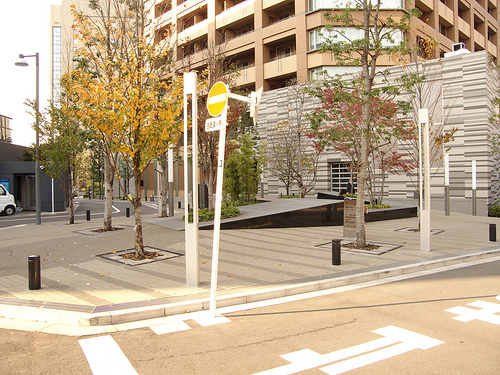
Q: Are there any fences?
A: No, there are no fences.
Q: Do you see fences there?
A: No, there are no fences.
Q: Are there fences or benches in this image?
A: No, there are no fences or benches.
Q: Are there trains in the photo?
A: No, there are no trains.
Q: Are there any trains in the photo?
A: No, there are no trains.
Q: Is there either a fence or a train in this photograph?
A: No, there are no trains or fences.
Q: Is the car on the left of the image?
A: Yes, the car is on the left of the image.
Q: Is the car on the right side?
A: No, the car is on the left of the image.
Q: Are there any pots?
A: No, there are no pots.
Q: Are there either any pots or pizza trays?
A: No, there are no pots or pizza trays.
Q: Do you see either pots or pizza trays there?
A: No, there are no pots or pizza trays.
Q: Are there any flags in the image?
A: No, there are no flags.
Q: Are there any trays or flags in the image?
A: No, there are no flags or trays.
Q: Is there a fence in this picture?
A: No, there are no fences.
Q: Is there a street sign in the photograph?
A: Yes, there is a street sign.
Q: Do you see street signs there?
A: Yes, there is a street sign.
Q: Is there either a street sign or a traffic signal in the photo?
A: Yes, there is a street sign.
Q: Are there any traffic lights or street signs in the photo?
A: Yes, there is a street sign.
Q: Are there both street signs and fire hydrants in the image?
A: No, there is a street sign but no fire hydrants.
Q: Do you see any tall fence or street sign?
A: Yes, there is a tall street sign.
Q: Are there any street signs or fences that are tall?
A: Yes, the street sign is tall.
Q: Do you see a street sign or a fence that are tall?
A: Yes, the street sign is tall.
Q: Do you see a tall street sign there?
A: Yes, there is a tall street sign.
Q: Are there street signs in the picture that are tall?
A: Yes, there is a street sign that is tall.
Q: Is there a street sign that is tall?
A: Yes, there is a street sign that is tall.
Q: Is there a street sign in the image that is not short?
A: Yes, there is a tall street sign.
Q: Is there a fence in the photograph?
A: No, there are no fences.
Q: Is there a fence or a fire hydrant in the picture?
A: No, there are no fences or fire hydrants.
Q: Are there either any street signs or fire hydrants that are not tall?
A: No, there is a street sign but it is tall.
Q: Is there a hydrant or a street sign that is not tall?
A: No, there is a street sign but it is tall.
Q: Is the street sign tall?
A: Yes, the street sign is tall.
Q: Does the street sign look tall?
A: Yes, the street sign is tall.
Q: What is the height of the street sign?
A: The street sign is tall.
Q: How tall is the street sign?
A: The street sign is tall.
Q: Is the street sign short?
A: No, the street sign is tall.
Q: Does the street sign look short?
A: No, the street sign is tall.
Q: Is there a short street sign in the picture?
A: No, there is a street sign but it is tall.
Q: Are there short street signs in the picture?
A: No, there is a street sign but it is tall.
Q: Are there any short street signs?
A: No, there is a street sign but it is tall.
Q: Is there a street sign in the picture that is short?
A: No, there is a street sign but it is tall.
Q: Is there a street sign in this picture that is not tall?
A: No, there is a street sign but it is tall.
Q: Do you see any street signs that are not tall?
A: No, there is a street sign but it is tall.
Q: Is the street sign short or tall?
A: The street sign is tall.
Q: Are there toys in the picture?
A: No, there are no toys.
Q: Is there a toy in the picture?
A: No, there are no toys.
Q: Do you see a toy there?
A: No, there are no toys.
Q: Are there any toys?
A: No, there are no toys.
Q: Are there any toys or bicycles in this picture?
A: No, there are no toys or bicycles.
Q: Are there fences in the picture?
A: No, there are no fences.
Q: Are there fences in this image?
A: No, there are no fences.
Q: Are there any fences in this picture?
A: No, there are no fences.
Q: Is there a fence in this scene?
A: No, there are no fences.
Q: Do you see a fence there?
A: No, there are no fences.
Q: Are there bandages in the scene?
A: No, there are no bandages.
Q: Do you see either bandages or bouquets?
A: No, there are no bandages or bouquets.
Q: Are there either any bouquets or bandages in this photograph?
A: No, there are no bandages or bouquets.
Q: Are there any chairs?
A: No, there are no chairs.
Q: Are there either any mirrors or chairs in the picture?
A: No, there are no chairs or mirrors.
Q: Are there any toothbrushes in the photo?
A: No, there are no toothbrushes.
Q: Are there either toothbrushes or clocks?
A: No, there are no toothbrushes or clocks.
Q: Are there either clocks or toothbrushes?
A: No, there are no toothbrushes or clocks.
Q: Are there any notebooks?
A: No, there are no notebooks.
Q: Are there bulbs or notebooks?
A: No, there are no notebooks or bulbs.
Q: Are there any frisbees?
A: No, there are no frisbees.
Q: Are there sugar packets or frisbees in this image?
A: No, there are no frisbees or sugar packets.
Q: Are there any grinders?
A: No, there are no grinders.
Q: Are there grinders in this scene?
A: No, there are no grinders.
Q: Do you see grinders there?
A: No, there are no grinders.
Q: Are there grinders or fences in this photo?
A: No, there are no grinders or fences.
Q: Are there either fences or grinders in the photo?
A: No, there are no grinders or fences.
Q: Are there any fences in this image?
A: No, there are no fences.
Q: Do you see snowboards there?
A: No, there are no snowboards.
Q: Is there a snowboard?
A: No, there are no snowboards.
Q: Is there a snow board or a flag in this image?
A: No, there are no snowboards or flags.